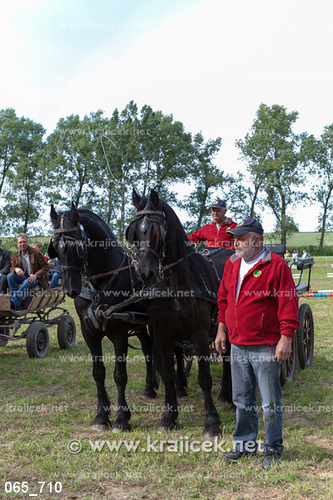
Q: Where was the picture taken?
A: It was taken at the park.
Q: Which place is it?
A: It is a park.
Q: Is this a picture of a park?
A: Yes, it is showing a park.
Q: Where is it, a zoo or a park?
A: It is a park.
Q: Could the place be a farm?
A: No, it is a park.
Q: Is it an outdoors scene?
A: Yes, it is outdoors.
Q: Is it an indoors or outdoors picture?
A: It is outdoors.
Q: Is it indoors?
A: No, it is outdoors.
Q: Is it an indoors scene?
A: No, it is outdoors.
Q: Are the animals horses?
A: Yes, all the animals are horses.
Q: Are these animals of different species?
A: No, all the animals are horses.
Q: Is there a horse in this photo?
A: Yes, there is a horse.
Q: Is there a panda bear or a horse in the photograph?
A: Yes, there is a horse.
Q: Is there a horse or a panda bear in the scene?
A: Yes, there is a horse.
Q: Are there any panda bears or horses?
A: Yes, there is a horse.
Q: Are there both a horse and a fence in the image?
A: No, there is a horse but no fences.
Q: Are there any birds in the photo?
A: No, there are no birds.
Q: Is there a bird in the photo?
A: No, there are no birds.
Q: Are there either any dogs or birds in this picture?
A: No, there are no birds or dogs.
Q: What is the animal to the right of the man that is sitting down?
A: The animal is a horse.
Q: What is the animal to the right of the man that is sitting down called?
A: The animal is a horse.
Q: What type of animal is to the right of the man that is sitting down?
A: The animal is a horse.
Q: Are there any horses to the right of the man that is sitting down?
A: Yes, there is a horse to the right of the man.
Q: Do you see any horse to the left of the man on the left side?
A: No, the horse is to the right of the man.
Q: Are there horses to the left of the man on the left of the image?
A: No, the horse is to the right of the man.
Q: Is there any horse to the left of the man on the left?
A: No, the horse is to the right of the man.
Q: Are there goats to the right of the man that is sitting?
A: No, there is a horse to the right of the man.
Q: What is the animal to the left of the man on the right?
A: The animal is a horse.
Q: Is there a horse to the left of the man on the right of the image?
A: Yes, there is a horse to the left of the man.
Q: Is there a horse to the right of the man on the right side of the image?
A: No, the horse is to the left of the man.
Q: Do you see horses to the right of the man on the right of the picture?
A: No, the horse is to the left of the man.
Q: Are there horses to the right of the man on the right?
A: No, the horse is to the left of the man.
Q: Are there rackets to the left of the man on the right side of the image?
A: No, there is a horse to the left of the man.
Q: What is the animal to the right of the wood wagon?
A: The animal is a horse.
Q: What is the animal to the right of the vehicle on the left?
A: The animal is a horse.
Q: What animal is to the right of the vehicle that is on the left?
A: The animal is a horse.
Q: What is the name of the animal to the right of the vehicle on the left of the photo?
A: The animal is a horse.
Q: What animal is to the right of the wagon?
A: The animal is a horse.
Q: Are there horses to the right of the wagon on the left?
A: Yes, there is a horse to the right of the wagon.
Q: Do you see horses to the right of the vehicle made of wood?
A: Yes, there is a horse to the right of the wagon.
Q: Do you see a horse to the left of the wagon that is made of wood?
A: No, the horse is to the right of the wagon.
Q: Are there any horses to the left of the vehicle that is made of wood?
A: No, the horse is to the right of the wagon.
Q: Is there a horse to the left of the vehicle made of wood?
A: No, the horse is to the right of the wagon.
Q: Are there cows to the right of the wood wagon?
A: No, there is a horse to the right of the wagon.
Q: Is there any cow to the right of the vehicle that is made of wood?
A: No, there is a horse to the right of the wagon.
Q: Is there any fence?
A: No, there are no fences.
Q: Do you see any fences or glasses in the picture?
A: No, there are no fences or glasses.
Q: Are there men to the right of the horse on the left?
A: Yes, there is a man to the right of the horse.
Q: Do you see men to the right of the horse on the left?
A: Yes, there is a man to the right of the horse.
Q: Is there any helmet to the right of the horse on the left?
A: No, there is a man to the right of the horse.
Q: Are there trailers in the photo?
A: No, there are no trailers.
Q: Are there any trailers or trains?
A: No, there are no trailers or trains.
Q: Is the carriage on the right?
A: Yes, the carriage is on the right of the image.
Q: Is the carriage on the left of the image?
A: No, the carriage is on the right of the image.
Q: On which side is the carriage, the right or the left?
A: The carriage is on the right of the image.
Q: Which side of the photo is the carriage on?
A: The carriage is on the right of the image.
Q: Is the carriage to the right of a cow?
A: No, the carriage is to the right of the horse.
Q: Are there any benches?
A: No, there are no benches.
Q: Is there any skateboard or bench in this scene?
A: No, there are no benches or skateboards.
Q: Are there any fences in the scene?
A: No, there are no fences.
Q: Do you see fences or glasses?
A: No, there are no fences or glasses.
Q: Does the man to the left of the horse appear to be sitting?
A: Yes, the man is sitting.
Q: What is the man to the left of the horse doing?
A: The man is sitting.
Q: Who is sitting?
A: The man is sitting.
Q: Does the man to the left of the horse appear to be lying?
A: No, the man is sitting.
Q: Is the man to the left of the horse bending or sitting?
A: The man is sitting.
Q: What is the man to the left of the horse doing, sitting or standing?
A: The man is sitting.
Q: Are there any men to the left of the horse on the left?
A: Yes, there is a man to the left of the horse.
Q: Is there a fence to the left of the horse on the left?
A: No, there is a man to the left of the horse.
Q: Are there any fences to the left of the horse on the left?
A: No, there is a man to the left of the horse.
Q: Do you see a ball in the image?
A: No, there are no balls.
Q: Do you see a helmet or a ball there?
A: No, there are no balls or helmets.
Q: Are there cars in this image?
A: No, there are no cars.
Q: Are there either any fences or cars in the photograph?
A: No, there are no cars or fences.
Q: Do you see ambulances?
A: No, there are no ambulances.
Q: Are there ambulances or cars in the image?
A: No, there are no ambulances or cars.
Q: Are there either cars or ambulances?
A: No, there are no ambulances or cars.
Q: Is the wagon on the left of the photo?
A: Yes, the wagon is on the left of the image.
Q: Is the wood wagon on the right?
A: No, the wagon is on the left of the image.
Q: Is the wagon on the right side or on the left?
A: The wagon is on the left of the image.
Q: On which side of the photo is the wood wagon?
A: The wagon is on the left of the image.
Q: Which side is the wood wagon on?
A: The wagon is on the left of the image.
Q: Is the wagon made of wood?
A: Yes, the wagon is made of wood.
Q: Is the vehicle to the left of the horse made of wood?
A: Yes, the wagon is made of wood.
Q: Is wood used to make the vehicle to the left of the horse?
A: Yes, the wagon is made of wood.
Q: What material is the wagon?
A: The wagon is made of wood.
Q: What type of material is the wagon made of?
A: The wagon is made of wood.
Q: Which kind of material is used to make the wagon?
A: The wagon is made of wood.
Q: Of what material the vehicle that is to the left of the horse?
A: The wagon is made of wood.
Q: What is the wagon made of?
A: The wagon is made of wood.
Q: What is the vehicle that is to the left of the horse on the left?
A: The vehicle is a wagon.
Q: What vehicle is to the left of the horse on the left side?
A: The vehicle is a wagon.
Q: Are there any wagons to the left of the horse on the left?
A: Yes, there is a wagon to the left of the horse.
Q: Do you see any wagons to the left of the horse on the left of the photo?
A: Yes, there is a wagon to the left of the horse.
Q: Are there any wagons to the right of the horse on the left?
A: No, the wagon is to the left of the horse.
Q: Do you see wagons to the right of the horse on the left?
A: No, the wagon is to the left of the horse.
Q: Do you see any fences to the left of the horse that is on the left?
A: No, there is a wagon to the left of the horse.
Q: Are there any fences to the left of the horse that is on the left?
A: No, there is a wagon to the left of the horse.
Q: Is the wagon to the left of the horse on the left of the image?
A: Yes, the wagon is to the left of the horse.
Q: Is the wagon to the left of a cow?
A: No, the wagon is to the left of the horse.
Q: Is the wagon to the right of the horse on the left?
A: No, the wagon is to the left of the horse.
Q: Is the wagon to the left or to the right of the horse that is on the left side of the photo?
A: The wagon is to the left of the horse.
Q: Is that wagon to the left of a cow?
A: No, the wagon is to the left of the horse.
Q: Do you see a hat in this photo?
A: Yes, there is a hat.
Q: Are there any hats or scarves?
A: Yes, there is a hat.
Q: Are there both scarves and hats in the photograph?
A: No, there is a hat but no scarves.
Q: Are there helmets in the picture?
A: No, there are no helmets.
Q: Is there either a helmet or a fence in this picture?
A: No, there are no helmets or fences.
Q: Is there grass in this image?
A: Yes, there is grass.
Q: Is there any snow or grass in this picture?
A: Yes, there is grass.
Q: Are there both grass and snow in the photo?
A: No, there is grass but no snow.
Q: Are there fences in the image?
A: No, there are no fences.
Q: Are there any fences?
A: No, there are no fences.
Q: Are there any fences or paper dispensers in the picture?
A: No, there are no fences or paper dispensers.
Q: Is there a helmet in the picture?
A: No, there are no helmets.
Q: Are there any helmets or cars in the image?
A: No, there are no helmets or cars.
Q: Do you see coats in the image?
A: Yes, there is a coat.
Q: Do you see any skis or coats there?
A: Yes, there is a coat.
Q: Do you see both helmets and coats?
A: No, there is a coat but no helmets.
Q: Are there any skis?
A: No, there are no skis.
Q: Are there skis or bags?
A: No, there are no skis or bags.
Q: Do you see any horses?
A: Yes, there is a horse.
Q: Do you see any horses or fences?
A: Yes, there is a horse.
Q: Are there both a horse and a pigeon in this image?
A: No, there is a horse but no pigeons.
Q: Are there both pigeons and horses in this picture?
A: No, there is a horse but no pigeons.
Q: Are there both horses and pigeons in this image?
A: No, there is a horse but no pigeons.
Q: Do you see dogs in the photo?
A: No, there are no dogs.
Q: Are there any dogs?
A: No, there are no dogs.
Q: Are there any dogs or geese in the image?
A: No, there are no dogs or geese.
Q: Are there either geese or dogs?
A: No, there are no dogs or geese.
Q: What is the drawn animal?
A: The animal is a horse.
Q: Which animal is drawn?
A: The animal is a horse.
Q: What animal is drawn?
A: The animal is a horse.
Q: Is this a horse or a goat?
A: This is a horse.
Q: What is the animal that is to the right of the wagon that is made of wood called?
A: The animal is a horse.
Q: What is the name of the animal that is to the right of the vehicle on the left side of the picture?
A: The animal is a horse.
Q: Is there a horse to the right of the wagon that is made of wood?
A: Yes, there is a horse to the right of the wagon.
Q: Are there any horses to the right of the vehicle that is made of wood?
A: Yes, there is a horse to the right of the wagon.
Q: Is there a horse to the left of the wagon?
A: No, the horse is to the right of the wagon.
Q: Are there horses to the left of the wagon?
A: No, the horse is to the right of the wagon.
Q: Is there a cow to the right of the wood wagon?
A: No, there is a horse to the right of the wagon.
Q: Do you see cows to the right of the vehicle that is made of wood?
A: No, there is a horse to the right of the wagon.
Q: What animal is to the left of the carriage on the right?
A: The animal is a horse.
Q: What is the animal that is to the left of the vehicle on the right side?
A: The animal is a horse.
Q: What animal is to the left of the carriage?
A: The animal is a horse.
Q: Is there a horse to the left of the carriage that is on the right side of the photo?
A: Yes, there is a horse to the left of the carriage.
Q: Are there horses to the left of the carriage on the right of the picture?
A: Yes, there is a horse to the left of the carriage.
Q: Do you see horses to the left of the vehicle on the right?
A: Yes, there is a horse to the left of the carriage.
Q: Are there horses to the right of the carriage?
A: No, the horse is to the left of the carriage.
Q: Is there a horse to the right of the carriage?
A: No, the horse is to the left of the carriage.